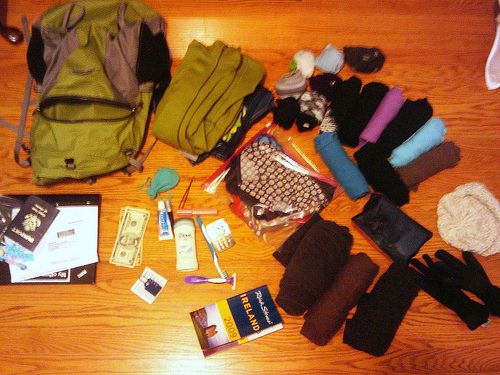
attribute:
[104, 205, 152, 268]
money — on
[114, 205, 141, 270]
money — on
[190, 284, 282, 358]
book — ireland tour guide book 2009 edition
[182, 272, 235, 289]
razor — purple, white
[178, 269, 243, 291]
razor — white , purple 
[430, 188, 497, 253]
hat — colored , cloth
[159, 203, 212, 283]
deodorant — on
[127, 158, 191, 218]
bag — blue , small 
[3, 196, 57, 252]
passport — on, American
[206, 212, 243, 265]
medication — on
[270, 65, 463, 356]
collection — of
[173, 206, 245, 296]
toothbrush — blue , white 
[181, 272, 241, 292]
razor — on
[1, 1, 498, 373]
hardwood floor — light brown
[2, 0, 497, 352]
floor — is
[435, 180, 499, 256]
hat — white, lacy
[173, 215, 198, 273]
deodorant — dove brand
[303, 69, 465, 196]
clothes — on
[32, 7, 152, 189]
backpack — black , grey, green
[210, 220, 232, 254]
pills — yellow, small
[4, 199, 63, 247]
passport — on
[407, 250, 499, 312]
gloves — black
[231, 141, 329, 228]
ziploc bag — plastic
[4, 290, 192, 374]
floor — grained, wooden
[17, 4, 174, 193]
backpack — on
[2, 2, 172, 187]
backpack — olive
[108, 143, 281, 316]
items — on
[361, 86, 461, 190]
socks — colored